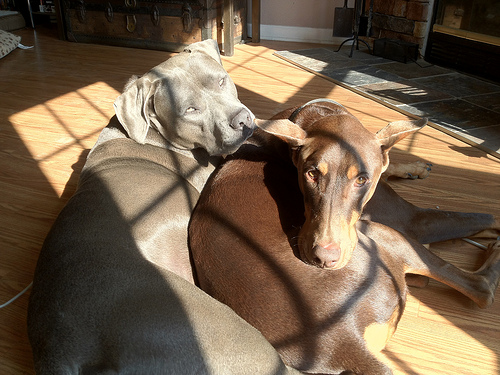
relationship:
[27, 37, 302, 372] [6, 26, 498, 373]
dog on floor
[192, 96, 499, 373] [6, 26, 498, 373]
dog on floor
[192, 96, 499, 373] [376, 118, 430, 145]
dog has ear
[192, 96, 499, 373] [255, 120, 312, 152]
dog has ear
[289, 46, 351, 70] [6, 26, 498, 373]
tile on floor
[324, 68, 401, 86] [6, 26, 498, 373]
tile on floor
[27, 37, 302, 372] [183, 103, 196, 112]
dog has eye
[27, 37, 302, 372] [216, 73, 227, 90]
dog has eye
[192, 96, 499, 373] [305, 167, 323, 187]
dog has eye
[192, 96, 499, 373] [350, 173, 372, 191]
dog has eye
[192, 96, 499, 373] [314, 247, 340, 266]
dog has nose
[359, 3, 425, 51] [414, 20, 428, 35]
wall made of brick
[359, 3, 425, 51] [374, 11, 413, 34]
wall made of brick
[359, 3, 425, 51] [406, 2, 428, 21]
wall made of brick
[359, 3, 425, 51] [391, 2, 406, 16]
wall made of brick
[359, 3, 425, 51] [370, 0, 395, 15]
wall made of brick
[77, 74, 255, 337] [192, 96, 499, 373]
light on dog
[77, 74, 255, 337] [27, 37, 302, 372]
light on dog